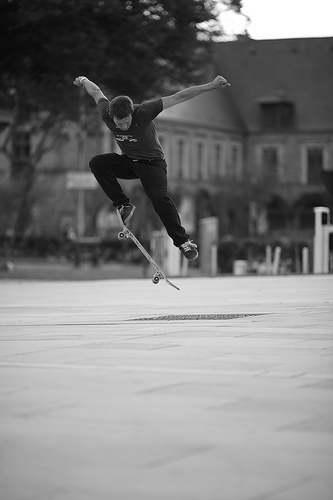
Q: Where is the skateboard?
A: In the air.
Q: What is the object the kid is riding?
A: Skateboard.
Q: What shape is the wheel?
A: Round.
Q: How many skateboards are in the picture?
A: One.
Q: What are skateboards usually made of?
A: Wood.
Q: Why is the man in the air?
A: He jumped.